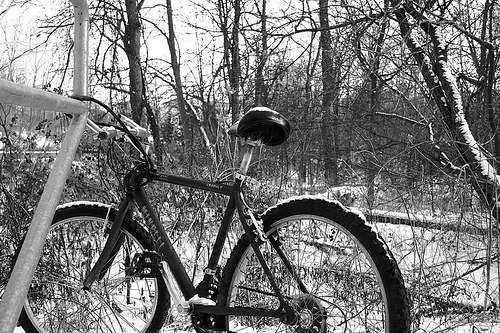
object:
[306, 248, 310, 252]
snow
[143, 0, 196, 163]
tree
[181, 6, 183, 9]
leaves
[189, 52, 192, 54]
leaves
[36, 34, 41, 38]
leaves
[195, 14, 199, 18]
leaves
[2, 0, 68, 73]
sky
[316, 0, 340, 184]
tree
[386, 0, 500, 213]
tree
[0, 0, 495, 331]
photo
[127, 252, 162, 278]
pedal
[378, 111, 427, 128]
branch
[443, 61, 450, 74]
snow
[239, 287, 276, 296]
chain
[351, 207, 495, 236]
pole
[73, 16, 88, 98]
bar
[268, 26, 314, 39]
branch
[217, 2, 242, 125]
tree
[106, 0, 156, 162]
tree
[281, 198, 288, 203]
snow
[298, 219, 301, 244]
spoke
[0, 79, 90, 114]
metal bar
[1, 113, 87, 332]
metal bar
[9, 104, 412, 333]
bicycle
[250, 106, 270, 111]
snow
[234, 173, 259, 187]
clamp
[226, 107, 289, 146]
seat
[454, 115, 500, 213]
trunk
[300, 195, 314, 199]
snow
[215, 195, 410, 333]
tire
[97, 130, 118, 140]
handlebar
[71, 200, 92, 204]
snow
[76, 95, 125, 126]
rope